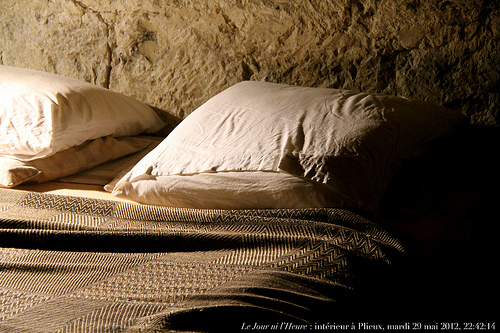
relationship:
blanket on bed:
[0, 190, 410, 330] [2, 65, 422, 329]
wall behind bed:
[3, 2, 498, 108] [2, 65, 422, 329]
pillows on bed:
[1, 65, 429, 209] [4, 109, 469, 329]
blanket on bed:
[0, 190, 410, 330] [1, 57, 451, 332]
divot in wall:
[343, 5, 380, 46] [104, 12, 297, 96]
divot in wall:
[432, 60, 453, 92] [1, 0, 499, 148]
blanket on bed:
[0, 190, 410, 330] [74, 131, 348, 308]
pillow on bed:
[100, 95, 412, 216] [47, 161, 292, 309]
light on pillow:
[0, 83, 56, 156] [0, 64, 167, 159]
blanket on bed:
[0, 138, 405, 331] [9, 144, 427, 331]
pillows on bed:
[1, 65, 429, 209] [9, 144, 427, 331]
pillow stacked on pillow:
[0, 62, 167, 187] [101, 80, 436, 210]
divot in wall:
[86, 148, 413, 321] [3, 5, 495, 179]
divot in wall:
[379, 45, 399, 87] [3, 2, 492, 129]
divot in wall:
[375, 44, 403, 88] [2, 6, 497, 249]